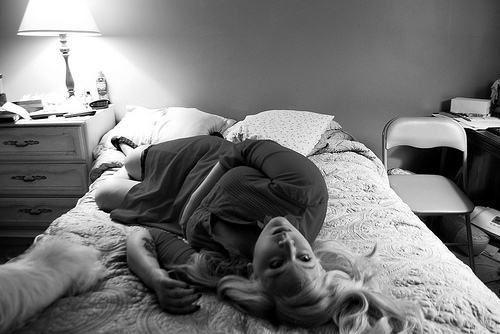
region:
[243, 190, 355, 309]
the head of a woman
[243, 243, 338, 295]
the eyes of a woman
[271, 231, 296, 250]
the nose of a woman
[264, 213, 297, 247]
the mouth of a woman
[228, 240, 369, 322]
the hair of a woman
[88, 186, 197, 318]
the arm of a woman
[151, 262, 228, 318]
the hand of a woman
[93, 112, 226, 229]
the legs of a woman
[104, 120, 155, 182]
the shoe of a woman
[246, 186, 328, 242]
the chin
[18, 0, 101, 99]
lamp on night stand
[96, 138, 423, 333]
lady wearing a dress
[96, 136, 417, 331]
lady with blonde hair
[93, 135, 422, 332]
lady laying on bed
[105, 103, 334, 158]
pillows on a bed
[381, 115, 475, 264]
a folding metal chair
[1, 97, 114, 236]
a light color night stand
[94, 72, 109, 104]
a cordless telephone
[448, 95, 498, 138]
clutter on table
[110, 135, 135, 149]
a dark female slip on shoe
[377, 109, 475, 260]
Chair next to the bed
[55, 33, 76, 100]
Bottom half of lamp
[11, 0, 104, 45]
Lamp shade part of the lamp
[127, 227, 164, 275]
Arm with the tattoo on it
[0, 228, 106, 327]
Half of a dog on the bed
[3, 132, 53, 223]
Four handles on a dresser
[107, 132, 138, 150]
Black shoe on womans foot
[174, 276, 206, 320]
Painted finger nails on the woman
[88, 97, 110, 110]
Black alarm clock on dresser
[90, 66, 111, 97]
Water bottle next to the wall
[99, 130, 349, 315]
A woman laying on the bed.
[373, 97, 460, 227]
Chair next to the bed.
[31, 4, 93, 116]
A lamp on the nightstad.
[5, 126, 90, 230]
Three drawers on the nightstand.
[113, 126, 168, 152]
The girl has on shoes.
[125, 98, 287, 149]
Pillows on the bed.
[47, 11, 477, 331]
The picture is in black and white.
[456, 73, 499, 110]
Small box on the table.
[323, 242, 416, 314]
The girl has long blonde hair.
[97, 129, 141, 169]
The girl foot on the pillow.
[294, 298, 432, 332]
the womans blonde hair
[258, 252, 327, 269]
the womans eyes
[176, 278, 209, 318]
the womans painted fingernails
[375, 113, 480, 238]
a fold up chair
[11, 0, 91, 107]
a lamp on the night stand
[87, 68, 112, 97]
a cordless phone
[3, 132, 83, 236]
the drawers on the night stand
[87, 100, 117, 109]
an alarm clock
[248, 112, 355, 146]
pillows on the bed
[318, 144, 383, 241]
the cover on the bed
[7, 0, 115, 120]
a lamp that is on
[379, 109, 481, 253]
a white folding chair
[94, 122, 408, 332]
a blonde woman laying on a bed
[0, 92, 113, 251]
nightstand with three drawers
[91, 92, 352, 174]
pillows on a bed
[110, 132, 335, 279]
a dress worn by a woman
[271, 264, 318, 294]
the forehead of a woman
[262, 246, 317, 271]
the eyes of a woman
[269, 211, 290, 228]
the chin of a woman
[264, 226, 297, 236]
the lips of a woman